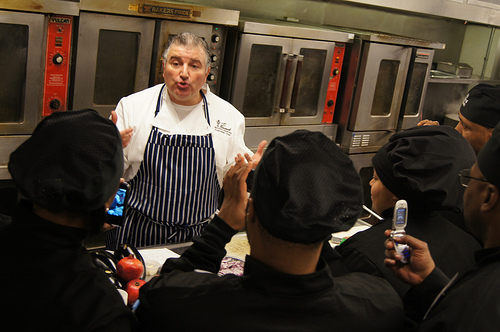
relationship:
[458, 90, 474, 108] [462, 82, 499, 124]
writing on hat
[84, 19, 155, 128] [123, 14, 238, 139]
window behind man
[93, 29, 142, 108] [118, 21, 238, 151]
window behind man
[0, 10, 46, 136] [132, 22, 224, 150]
oven door behind man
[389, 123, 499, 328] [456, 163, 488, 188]
man wearing glasses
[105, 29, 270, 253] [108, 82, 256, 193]
man wearing shirt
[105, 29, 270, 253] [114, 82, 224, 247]
man wearing apron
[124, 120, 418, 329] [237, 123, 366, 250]
man wearing black hat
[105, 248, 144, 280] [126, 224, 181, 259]
apple sitting on counter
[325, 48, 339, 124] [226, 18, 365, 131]
knobs on oven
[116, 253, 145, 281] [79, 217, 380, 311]
apple sitting on counter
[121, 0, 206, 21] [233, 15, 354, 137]
sign on oven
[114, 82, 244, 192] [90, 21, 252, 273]
shirt on chef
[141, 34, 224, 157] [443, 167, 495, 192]
man wearing glasses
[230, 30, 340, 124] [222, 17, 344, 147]
doors on oven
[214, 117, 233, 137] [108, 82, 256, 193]
black writing on side of shirt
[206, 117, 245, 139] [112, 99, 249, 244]
logo on side of shirt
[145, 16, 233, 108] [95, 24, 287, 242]
head of man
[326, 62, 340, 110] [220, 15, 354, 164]
knobs on side of oven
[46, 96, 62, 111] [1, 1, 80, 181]
knobs on side of oven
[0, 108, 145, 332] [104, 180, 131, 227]
man holding cell phone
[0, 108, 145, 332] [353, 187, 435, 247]
man holding phone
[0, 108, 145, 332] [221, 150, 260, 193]
man holding cell phone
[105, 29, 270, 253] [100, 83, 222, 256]
man wearing apron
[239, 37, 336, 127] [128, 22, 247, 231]
oven door behind man